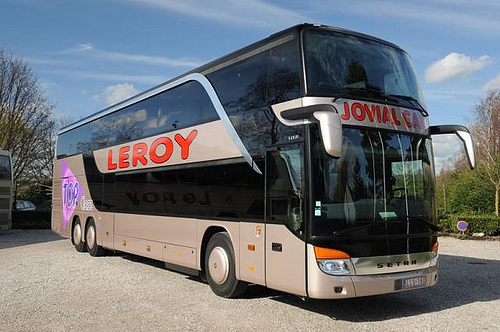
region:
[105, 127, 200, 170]
THE WORD LEROY ON THE SIDE OF THE BUS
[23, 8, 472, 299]
a large bus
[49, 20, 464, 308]
a large tan bus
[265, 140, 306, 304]
the door to get on the bus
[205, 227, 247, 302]
the front tire of the bus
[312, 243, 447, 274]
the headlights for the bus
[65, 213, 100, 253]
the back tires of the bus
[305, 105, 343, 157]
the passenger side rear view mirror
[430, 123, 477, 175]
the drivers die rear view mirror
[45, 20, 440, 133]
the roof of the bus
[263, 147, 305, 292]
A door on the bus.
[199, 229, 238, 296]
The tire on a bus.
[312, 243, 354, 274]
Head light on a bus.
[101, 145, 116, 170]
A red letter L.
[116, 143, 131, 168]
A red letter E.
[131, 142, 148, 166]
A red letter R.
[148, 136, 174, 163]
A red letter O.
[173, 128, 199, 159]
A red letter Y.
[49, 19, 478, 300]
A bus in a parking lot.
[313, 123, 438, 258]
A windshield on a bus.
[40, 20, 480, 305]
Bus is parked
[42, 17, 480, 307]
Bus parked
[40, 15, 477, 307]
Double decker bus parked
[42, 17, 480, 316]
Double decker bus is parked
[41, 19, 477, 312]
Bus parked on a lot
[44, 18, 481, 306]
Bus is parked on a lot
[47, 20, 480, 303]
Double decker bus parked on a lot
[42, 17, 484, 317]
Double decker bus is parked on a lot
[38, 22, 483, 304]
Double decker bus parked on a gravel lot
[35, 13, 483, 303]
Double decker bus is parked on a gravel lot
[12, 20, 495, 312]
a large touring bus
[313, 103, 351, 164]
the side mirror of a large bus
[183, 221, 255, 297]
the tire and wheel of a bus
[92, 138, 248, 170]
a sign that says Leroy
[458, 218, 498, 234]
a well trimmed hedge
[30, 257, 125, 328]
a gravel parking lot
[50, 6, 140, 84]
a blue sky with wispy clouds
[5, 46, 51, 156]
a tree without many leaves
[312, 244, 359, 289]
the headlight of a large bus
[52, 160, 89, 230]
a purple decal on the side of a bus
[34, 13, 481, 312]
The bus is tall.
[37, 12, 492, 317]
All of the windows in the bus are tinted.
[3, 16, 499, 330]
The bus is sitting on gravel.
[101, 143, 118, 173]
The letter is red.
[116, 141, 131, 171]
The letter is red.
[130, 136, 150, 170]
The letter is red.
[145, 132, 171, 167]
The letter is red.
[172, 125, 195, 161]
The letter is red.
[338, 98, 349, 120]
The letter is red.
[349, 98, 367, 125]
The letter is red.